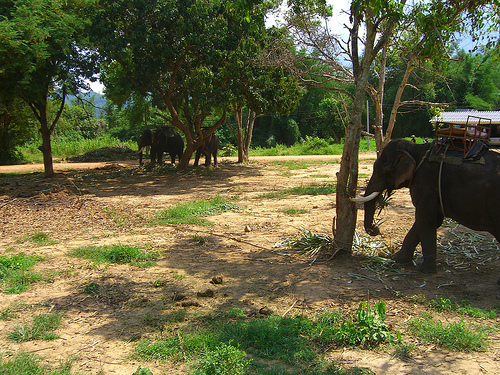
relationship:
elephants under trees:
[107, 120, 248, 158] [15, 29, 368, 121]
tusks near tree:
[340, 186, 378, 202] [324, 44, 382, 252]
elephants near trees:
[107, 120, 248, 158] [15, 29, 368, 121]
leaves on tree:
[425, 16, 432, 66] [324, 44, 382, 252]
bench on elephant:
[424, 121, 492, 152] [353, 125, 500, 254]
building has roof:
[424, 97, 498, 145] [440, 109, 498, 122]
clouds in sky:
[314, 1, 350, 37] [257, 0, 491, 44]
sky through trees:
[257, 0, 491, 44] [15, 29, 368, 121]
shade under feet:
[150, 166, 259, 186] [193, 160, 229, 168]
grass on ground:
[198, 311, 331, 348] [43, 272, 457, 367]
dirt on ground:
[48, 178, 218, 218] [43, 272, 457, 367]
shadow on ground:
[162, 219, 323, 304] [43, 272, 457, 367]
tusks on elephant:
[340, 186, 378, 202] [353, 125, 500, 254]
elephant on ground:
[353, 125, 500, 254] [43, 272, 457, 367]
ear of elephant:
[396, 145, 426, 192] [353, 125, 500, 254]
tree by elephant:
[324, 44, 382, 252] [353, 125, 500, 254]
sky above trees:
[257, 0, 491, 44] [15, 29, 368, 121]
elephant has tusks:
[353, 125, 500, 254] [340, 186, 378, 202]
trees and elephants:
[15, 29, 368, 121] [107, 120, 248, 158]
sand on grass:
[176, 232, 268, 278] [198, 311, 331, 348]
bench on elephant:
[434, 114, 492, 158] [353, 125, 500, 254]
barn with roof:
[424, 97, 498, 145] [440, 109, 498, 122]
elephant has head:
[353, 125, 500, 254] [356, 128, 409, 219]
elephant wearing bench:
[353, 125, 500, 254] [434, 114, 492, 158]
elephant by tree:
[353, 125, 500, 254] [324, 44, 382, 252]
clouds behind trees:
[314, 1, 350, 37] [15, 29, 368, 121]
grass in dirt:
[198, 311, 331, 348] [48, 178, 218, 218]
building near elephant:
[424, 97, 498, 145] [353, 125, 500, 254]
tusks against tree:
[340, 186, 378, 202] [324, 44, 382, 252]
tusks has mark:
[340, 186, 378, 202] [347, 175, 361, 207]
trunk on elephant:
[362, 189, 388, 236] [353, 125, 500, 254]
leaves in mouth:
[376, 192, 392, 213] [376, 185, 403, 202]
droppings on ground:
[161, 281, 236, 314] [43, 272, 457, 367]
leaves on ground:
[276, 236, 390, 274] [43, 272, 457, 367]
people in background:
[403, 128, 439, 147] [257, 54, 492, 140]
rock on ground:
[226, 218, 305, 241] [43, 272, 457, 367]